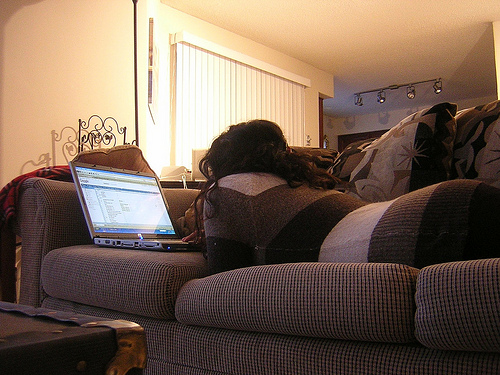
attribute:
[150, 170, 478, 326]
couch — brown, black, checkered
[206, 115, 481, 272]
sweater — brown, black, white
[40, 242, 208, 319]
cushion — brown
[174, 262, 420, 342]
cushion — brown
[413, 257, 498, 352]
cushion — brown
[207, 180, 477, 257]
sweater — striped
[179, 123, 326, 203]
hair — long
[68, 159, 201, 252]
laptop — silver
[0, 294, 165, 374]
table — trunk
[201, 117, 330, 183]
hair — dark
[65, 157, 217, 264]
laptop — silver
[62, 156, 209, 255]
laptop — on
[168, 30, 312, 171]
blinds — white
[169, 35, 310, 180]
blinds — white, vertical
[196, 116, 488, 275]
woman — laying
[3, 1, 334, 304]
wall — cream-colored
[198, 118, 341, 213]
hair — wavy, black